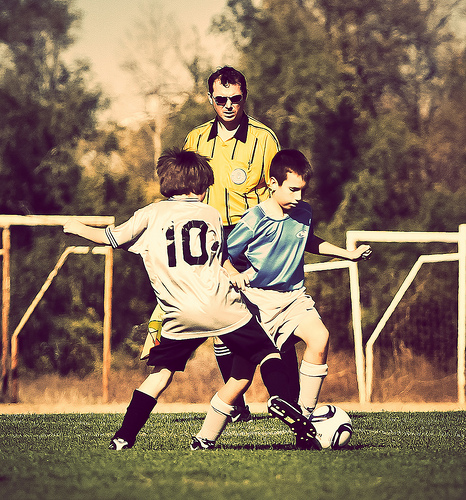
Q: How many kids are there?
A: Two.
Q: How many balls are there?
A: One.